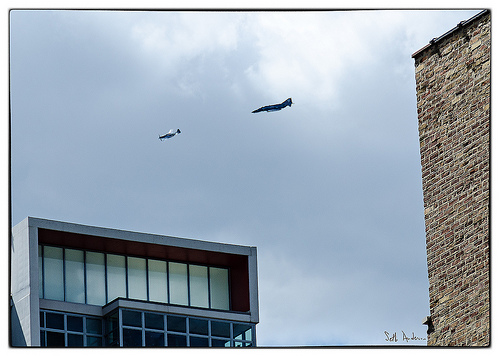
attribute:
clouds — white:
[115, 17, 345, 122]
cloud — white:
[105, 16, 386, 89]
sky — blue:
[11, 11, 483, 345]